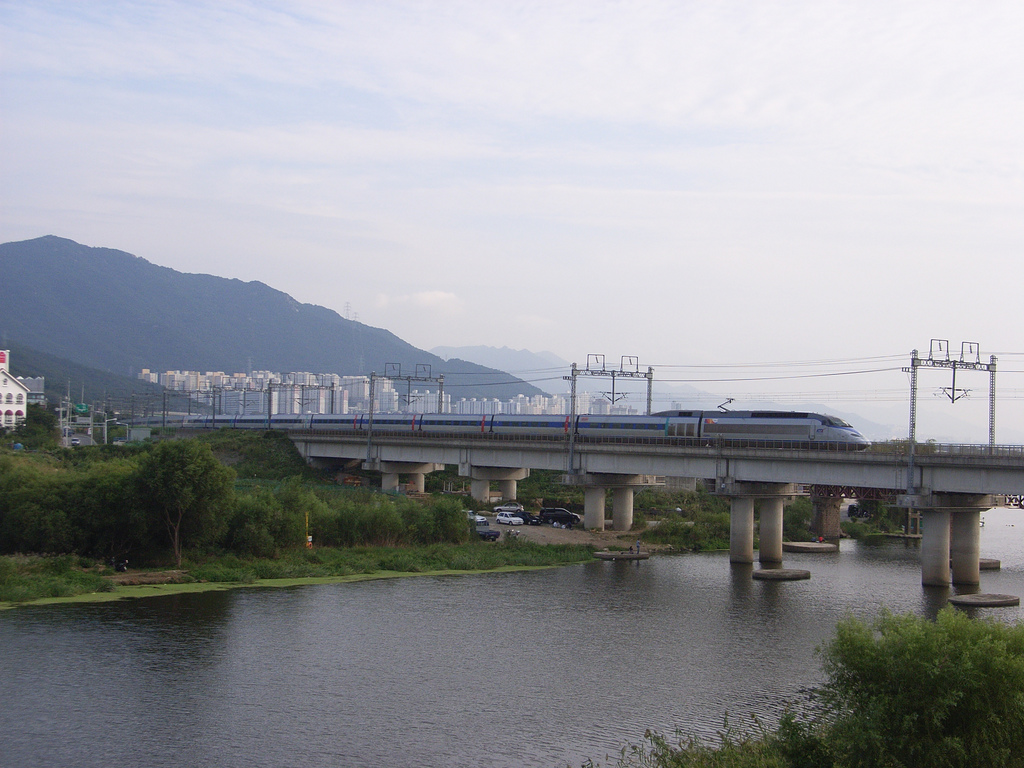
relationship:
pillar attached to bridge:
[377, 452, 417, 513] [156, 409, 1008, 608]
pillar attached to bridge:
[396, 437, 444, 509] [165, 413, 1019, 647]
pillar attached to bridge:
[491, 459, 533, 529] [178, 396, 1021, 604]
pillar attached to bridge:
[574, 476, 613, 548] [165, 413, 1019, 647]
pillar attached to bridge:
[595, 474, 662, 557] [232, 392, 1010, 654]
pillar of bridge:
[712, 487, 786, 565] [131, 374, 1007, 582]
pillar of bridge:
[913, 495, 959, 606] [144, 389, 1015, 564]